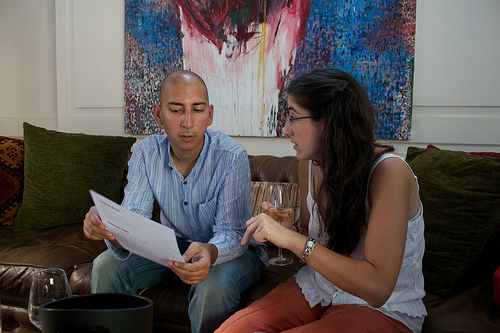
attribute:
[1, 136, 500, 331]
couch — brown, leather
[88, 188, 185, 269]
paper — white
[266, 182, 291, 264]
wine glass — clear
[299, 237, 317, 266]
watch — silver, metal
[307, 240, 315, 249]
face — white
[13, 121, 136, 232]
throw pillow — green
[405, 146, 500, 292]
throw pillow — green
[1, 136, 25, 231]
pillow — brown, black, red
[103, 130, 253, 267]
shirt — blue, striped, blue stripe, white, button down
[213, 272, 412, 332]
pants — orange, salmon, brown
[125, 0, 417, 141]
art — multicolored, colorful, abstract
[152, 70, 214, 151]
head — bald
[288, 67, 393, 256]
hair — long, dark, brown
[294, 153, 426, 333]
tank top — white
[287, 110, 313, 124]
glasses — black framed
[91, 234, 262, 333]
jeans — blue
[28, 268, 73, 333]
wine goblet — clear